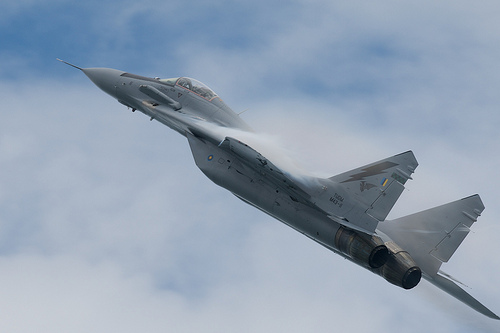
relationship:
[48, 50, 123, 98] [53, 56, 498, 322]
nose on jet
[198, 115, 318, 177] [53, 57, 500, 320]
smoke from jet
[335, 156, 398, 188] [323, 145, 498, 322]
lightning bolt on tail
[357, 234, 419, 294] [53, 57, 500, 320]
engine on jet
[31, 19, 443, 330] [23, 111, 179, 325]
sky with clouds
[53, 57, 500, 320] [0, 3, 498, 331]
jet flying in sky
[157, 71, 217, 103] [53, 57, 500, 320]
glass over cockpit of a jet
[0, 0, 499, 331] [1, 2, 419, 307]
cloud against sky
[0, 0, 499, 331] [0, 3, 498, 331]
cloud against sky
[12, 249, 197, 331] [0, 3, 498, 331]
cloud against sky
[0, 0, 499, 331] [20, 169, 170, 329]
cloud in sky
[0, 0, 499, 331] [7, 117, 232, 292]
cloud in sky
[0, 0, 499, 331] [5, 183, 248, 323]
cloud in sky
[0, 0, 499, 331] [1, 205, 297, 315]
cloud in sky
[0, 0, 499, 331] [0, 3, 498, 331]
cloud in sky